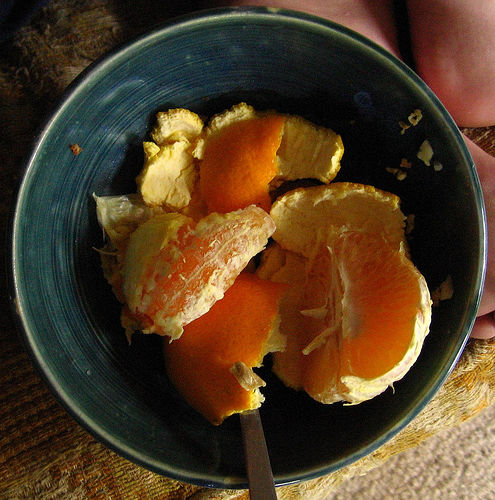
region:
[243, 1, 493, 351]
The person's feet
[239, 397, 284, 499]
The utensil in the bowl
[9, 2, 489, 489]
The bowl the orange is in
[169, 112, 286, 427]
The pieces of peel with the outside showing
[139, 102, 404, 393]
The pieces of peel with the inside showing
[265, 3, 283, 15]
The chip in the bowl's lip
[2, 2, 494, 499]
The couch the bowl in on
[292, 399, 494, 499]
The bit of carpet shown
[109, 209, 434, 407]
The meat of the orange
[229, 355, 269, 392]
An exposed orange seed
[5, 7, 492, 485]
the bowl is green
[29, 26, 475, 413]
oranges and orange peels are in the bowl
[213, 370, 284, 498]
a spoon is in the bowl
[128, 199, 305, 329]
the oranges have white skin on them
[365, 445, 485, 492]
the carpet is brown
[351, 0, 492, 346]
the person's feet are white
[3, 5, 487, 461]
the bowl is next to a person's feet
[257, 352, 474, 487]
the surface the bowl is on is yellow orange and white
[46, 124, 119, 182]
orange seeds are on the bowl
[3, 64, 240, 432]
the bowl has white spots on it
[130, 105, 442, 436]
orange broken into pieces in a bowl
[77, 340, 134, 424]
green ceramic bowl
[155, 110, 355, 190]
orange peels in bowl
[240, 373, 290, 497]
silver ware leaning on bowl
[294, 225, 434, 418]
peeled orange slices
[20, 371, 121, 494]
bowl sitting on top of fabric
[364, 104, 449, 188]
small pieces of orange on sides of bowl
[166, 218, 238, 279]
pieces of orange peel on orange slices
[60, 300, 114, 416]
small stripes around bowl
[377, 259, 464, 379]
light shining on oranges and bowl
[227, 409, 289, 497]
A utensil handle.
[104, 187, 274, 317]
Part of a peeled orange.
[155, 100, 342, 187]
The peal of the orange.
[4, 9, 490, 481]
A blue colored bowl.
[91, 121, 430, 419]
The orange is in the bowl.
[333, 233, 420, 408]
The segment of an orange.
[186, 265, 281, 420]
A fragment of an orange peal.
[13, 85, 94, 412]
Lines are visible in the blue glaze of the bowl.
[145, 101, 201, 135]
A tiny bit of orange peal.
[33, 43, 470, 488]
A bowl with an orange in it.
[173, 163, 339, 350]
oranges in a bowl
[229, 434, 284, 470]
a spoon that is in the bowl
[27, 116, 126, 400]
a bowl with fruit in it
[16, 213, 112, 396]
a green bowl on the counter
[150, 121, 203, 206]
some orange peel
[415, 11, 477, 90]
the hand of the man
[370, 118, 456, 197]
some peel that is on the side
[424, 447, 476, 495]
carpet on the ground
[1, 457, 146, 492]
the mat that the bowl is on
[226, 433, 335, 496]
hey a silver spoon